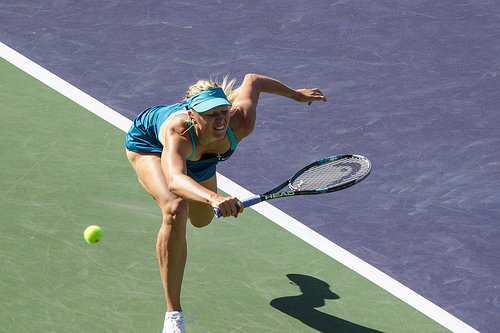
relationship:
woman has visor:
[120, 71, 329, 332] [172, 77, 240, 115]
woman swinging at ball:
[120, 71, 328, 331] [81, 222, 104, 247]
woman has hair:
[120, 71, 329, 332] [182, 65, 235, 97]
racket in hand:
[212, 150, 372, 217] [207, 196, 244, 219]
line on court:
[1, 40, 480, 331] [3, 1, 498, 331]